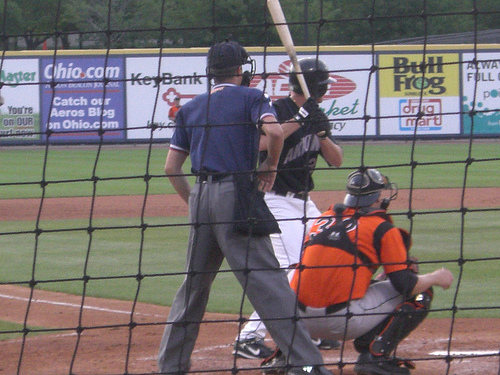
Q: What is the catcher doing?
A: Waiting on the ball.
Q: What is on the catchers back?
A: Straps to his vest.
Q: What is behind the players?
A: A black net.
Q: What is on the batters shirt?
A: Name of team.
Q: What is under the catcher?
A: Brown dirt.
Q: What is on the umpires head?
A: A safety mask.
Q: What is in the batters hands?
A: A base ball bat.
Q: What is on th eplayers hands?
A: Black gloves.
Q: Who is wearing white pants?
A: The man.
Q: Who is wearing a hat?
A: The man.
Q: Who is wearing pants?
A: The man.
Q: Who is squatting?
A: The man.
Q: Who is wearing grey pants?
A: The man.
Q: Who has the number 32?
A: Catcher.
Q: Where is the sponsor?
A: On wall.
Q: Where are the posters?
A: Wall.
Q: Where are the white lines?
A: Field.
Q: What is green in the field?
A: Grass.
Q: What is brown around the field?
A: Dirt.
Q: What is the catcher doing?
A: Crouching.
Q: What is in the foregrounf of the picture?
A: Black string of net.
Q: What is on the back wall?
A: Advertisments.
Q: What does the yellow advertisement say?
A: Bull Frog.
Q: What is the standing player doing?
A: Holding a bat.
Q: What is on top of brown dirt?
A: White lines.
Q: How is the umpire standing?
A: With spread legs.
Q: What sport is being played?
A: Baseball.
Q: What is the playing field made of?
A: Dirt and grass.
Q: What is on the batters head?
A: A helmet.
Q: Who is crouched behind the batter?
A: The catcher.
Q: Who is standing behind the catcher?
A: The umpire.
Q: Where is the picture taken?
A: A baseball field.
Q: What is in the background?
A: Advertisement.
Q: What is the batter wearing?
A: A black shirt.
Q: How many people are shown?
A: Three.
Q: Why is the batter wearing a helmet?
A: For protection.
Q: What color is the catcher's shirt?
A: Orange.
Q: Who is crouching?
A: The catcher.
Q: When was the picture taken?
A: At daytime.